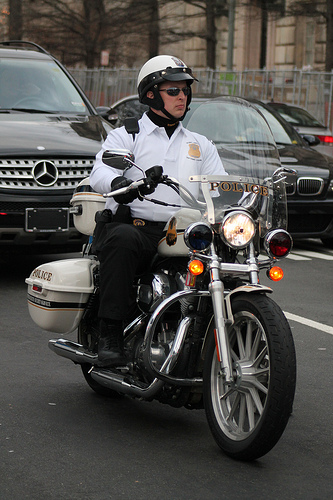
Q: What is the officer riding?
A: A motorcycle.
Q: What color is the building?
A: Tan.